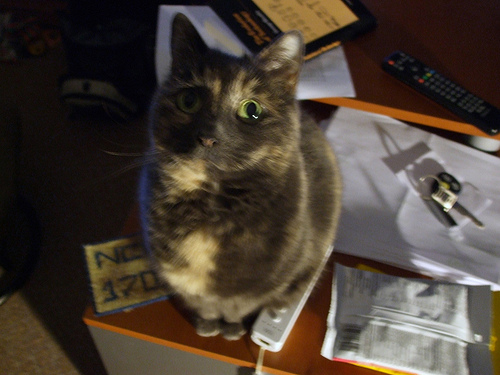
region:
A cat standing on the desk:
[136, 11, 336, 342]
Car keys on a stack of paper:
[415, 165, 483, 232]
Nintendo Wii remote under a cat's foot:
[253, 243, 333, 348]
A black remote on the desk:
[382, 48, 498, 134]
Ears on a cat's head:
[168, 13, 305, 90]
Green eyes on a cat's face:
[176, 88, 266, 123]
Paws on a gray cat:
[194, 318, 249, 341]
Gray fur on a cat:
[156, 173, 317, 270]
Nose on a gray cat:
[198, 134, 220, 149]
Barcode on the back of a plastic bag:
[337, 319, 361, 356]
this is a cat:
[160, 67, 360, 339]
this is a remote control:
[248, 303, 308, 344]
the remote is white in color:
[257, 319, 292, 343]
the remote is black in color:
[397, 67, 465, 115]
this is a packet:
[341, 264, 475, 372]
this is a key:
[399, 149, 471, 196]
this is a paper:
[347, 182, 407, 255]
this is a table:
[144, 307, 187, 349]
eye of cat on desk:
[230, 97, 272, 124]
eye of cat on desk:
[169, 90, 203, 113]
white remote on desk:
[254, 250, 334, 349]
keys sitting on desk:
[417, 165, 491, 232]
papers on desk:
[316, 109, 498, 290]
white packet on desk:
[328, 263, 487, 373]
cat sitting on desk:
[141, 17, 328, 347]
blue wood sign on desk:
[75, 246, 200, 313]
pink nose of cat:
[198, 135, 215, 147]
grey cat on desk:
[143, 15, 330, 339]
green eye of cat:
[238, 98, 261, 118]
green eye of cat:
[171, 88, 206, 114]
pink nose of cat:
[199, 138, 219, 150]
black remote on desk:
[380, 50, 497, 132]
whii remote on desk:
[250, 250, 347, 352]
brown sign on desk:
[78, 244, 175, 311]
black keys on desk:
[412, 170, 483, 235]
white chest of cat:
[170, 228, 221, 312]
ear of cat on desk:
[263, 28, 303, 102]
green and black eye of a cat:
[231, 91, 274, 125]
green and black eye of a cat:
[174, 79, 204, 120]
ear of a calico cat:
[256, 23, 306, 86]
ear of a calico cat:
[163, 10, 213, 61]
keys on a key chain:
[409, 159, 491, 247]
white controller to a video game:
[242, 233, 338, 374]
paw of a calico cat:
[221, 316, 246, 346]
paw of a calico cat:
[194, 315, 221, 339]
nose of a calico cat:
[195, 130, 222, 152]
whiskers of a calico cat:
[97, 140, 177, 187]